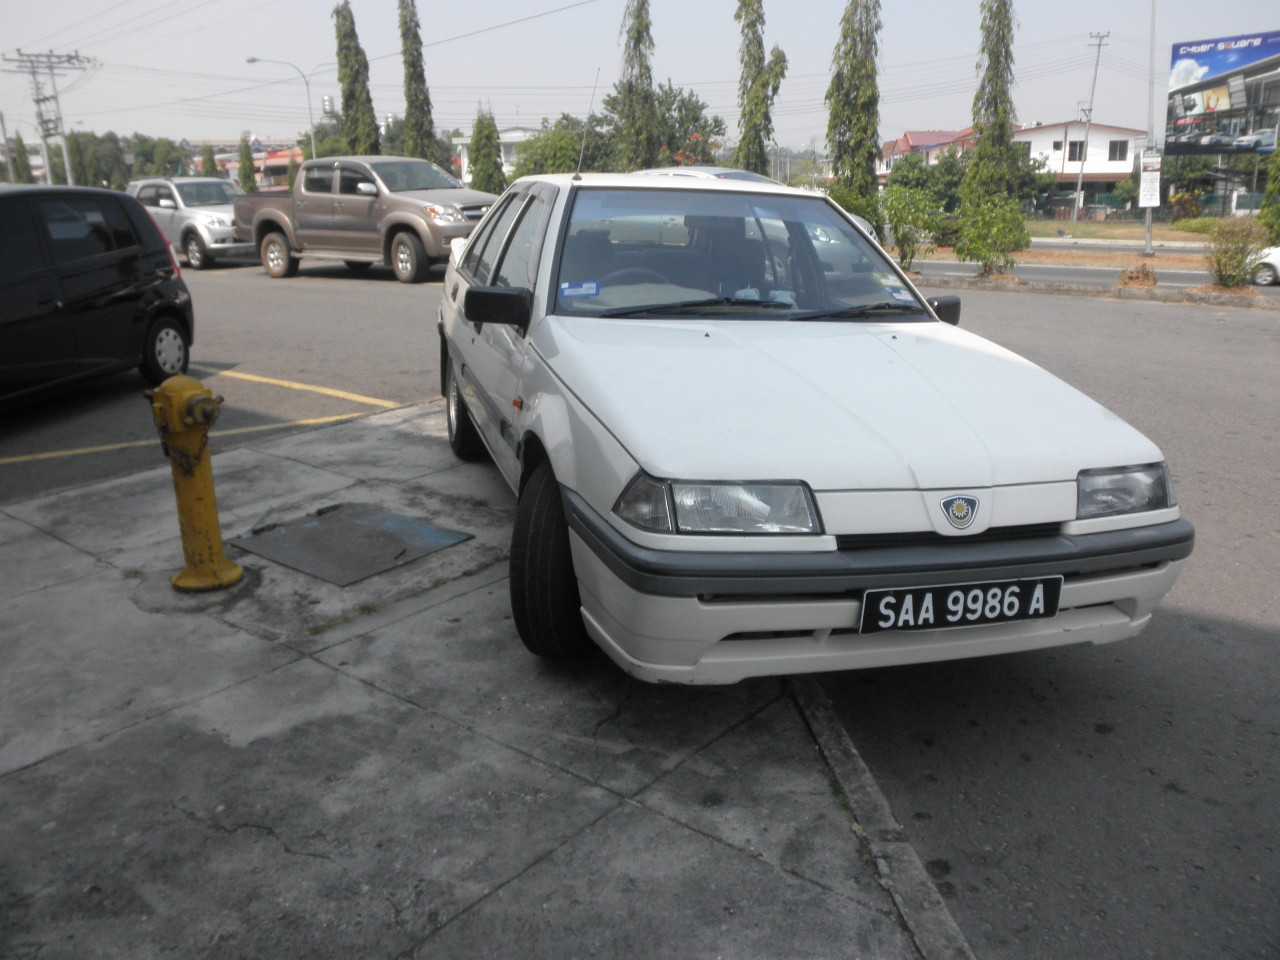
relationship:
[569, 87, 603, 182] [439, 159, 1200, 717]
antenna on car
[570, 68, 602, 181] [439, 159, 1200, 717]
antenna on car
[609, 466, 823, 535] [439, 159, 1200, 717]
light on car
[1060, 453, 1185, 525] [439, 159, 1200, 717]
light on car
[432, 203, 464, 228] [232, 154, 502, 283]
light on truck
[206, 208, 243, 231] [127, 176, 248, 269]
light on car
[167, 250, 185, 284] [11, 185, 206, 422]
light on car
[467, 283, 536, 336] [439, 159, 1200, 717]
mirror on car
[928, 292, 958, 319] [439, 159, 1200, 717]
mirror on car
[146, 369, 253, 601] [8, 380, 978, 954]
hydrant on sidewalk